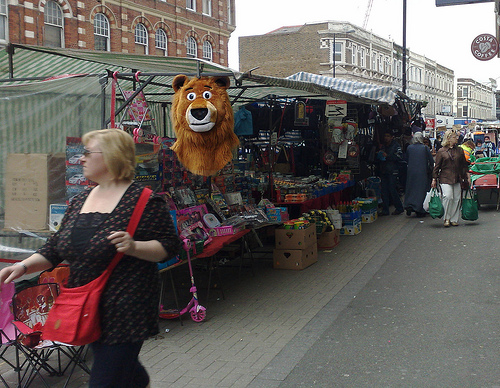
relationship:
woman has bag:
[0, 125, 178, 384] [23, 182, 155, 353]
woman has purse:
[0, 125, 178, 384] [40, 185, 153, 348]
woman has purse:
[0, 125, 186, 384] [40, 185, 153, 348]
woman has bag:
[0, 125, 178, 384] [37, 183, 156, 352]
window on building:
[88, 6, 115, 57] [1, 0, 240, 80]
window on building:
[127, 19, 148, 60] [1, 0, 240, 80]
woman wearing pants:
[0, 125, 186, 384] [81, 341, 152, 385]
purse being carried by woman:
[40, 185, 152, 340] [0, 125, 186, 384]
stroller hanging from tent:
[105, 69, 163, 151] [4, 73, 275, 299]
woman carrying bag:
[429, 129, 476, 230] [426, 191, 444, 217]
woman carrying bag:
[429, 129, 476, 230] [459, 194, 479, 221]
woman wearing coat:
[395, 124, 434, 217] [402, 139, 434, 215]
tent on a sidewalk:
[215, 59, 403, 200] [220, 295, 296, 384]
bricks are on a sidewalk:
[149, 345, 194, 367] [0, 207, 423, 386]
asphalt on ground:
[410, 329, 432, 343] [388, 272, 477, 374]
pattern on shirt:
[118, 209, 128, 220] [59, 213, 111, 257]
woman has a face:
[0, 125, 186, 384] [80, 149, 100, 177]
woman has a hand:
[0, 125, 186, 384] [109, 231, 138, 256]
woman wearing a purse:
[0, 125, 186, 384] [49, 292, 100, 348]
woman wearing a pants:
[0, 125, 186, 384] [101, 354, 151, 385]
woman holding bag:
[429, 129, 476, 230] [457, 193, 483, 223]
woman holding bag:
[429, 129, 476, 230] [424, 190, 445, 220]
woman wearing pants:
[433, 129, 475, 230] [441, 185, 467, 225]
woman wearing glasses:
[0, 125, 186, 384] [78, 147, 99, 158]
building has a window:
[257, 23, 432, 90] [329, 37, 346, 67]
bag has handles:
[459, 188, 482, 221] [462, 188, 476, 199]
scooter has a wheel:
[163, 259, 213, 319] [191, 304, 209, 323]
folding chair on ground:
[15, 291, 50, 323] [168, 338, 248, 374]